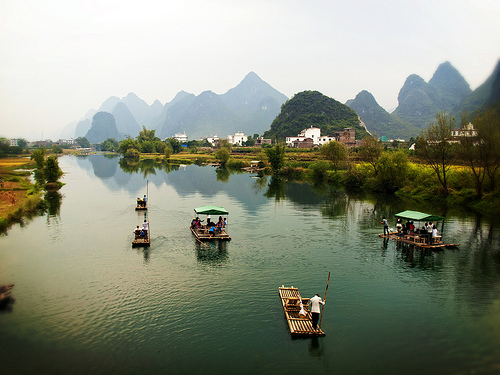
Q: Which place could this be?
A: It is a river.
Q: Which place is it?
A: It is a river.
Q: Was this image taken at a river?
A: Yes, it was taken in a river.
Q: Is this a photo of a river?
A: Yes, it is showing a river.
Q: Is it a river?
A: Yes, it is a river.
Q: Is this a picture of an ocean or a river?
A: It is showing a river.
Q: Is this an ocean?
A: No, it is a river.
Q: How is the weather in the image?
A: It is foggy.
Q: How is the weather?
A: It is foggy.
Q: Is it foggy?
A: Yes, it is foggy.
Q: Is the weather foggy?
A: Yes, it is foggy.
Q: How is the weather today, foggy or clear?
A: It is foggy.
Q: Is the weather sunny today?
A: No, it is foggy.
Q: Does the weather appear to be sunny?
A: No, it is foggy.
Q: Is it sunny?
A: No, it is foggy.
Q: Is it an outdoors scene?
A: Yes, it is outdoors.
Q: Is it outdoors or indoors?
A: It is outdoors.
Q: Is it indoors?
A: No, it is outdoors.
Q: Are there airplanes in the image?
A: No, there are no airplanes.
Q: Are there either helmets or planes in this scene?
A: No, there are no planes or helmets.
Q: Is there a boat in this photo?
A: Yes, there is a boat.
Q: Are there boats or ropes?
A: Yes, there is a boat.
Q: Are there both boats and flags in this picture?
A: No, there is a boat but no flags.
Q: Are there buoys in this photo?
A: No, there are no buoys.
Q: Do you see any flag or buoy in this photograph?
A: No, there are no buoys or flags.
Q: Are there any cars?
A: No, there are no cars.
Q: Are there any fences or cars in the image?
A: No, there are no cars or fences.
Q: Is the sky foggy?
A: Yes, the sky is foggy.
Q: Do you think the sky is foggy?
A: Yes, the sky is foggy.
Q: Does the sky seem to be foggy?
A: Yes, the sky is foggy.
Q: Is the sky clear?
A: No, the sky is foggy.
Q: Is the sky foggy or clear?
A: The sky is foggy.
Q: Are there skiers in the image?
A: No, there are no skiers.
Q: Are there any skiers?
A: No, there are no skiers.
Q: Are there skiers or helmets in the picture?
A: No, there are no skiers or helmets.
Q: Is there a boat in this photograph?
A: Yes, there is a boat.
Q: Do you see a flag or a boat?
A: Yes, there is a boat.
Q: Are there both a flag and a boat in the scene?
A: No, there is a boat but no flags.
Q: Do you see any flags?
A: No, there are no flags.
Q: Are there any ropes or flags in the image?
A: No, there are no flags or ropes.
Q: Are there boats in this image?
A: Yes, there is a boat.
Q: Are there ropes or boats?
A: Yes, there is a boat.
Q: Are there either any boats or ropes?
A: Yes, there is a boat.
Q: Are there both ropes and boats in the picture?
A: No, there is a boat but no ropes.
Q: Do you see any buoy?
A: No, there are no buoys.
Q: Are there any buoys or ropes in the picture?
A: No, there are no buoys or ropes.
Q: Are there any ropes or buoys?
A: No, there are no buoys or ropes.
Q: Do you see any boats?
A: Yes, there is a boat.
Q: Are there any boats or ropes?
A: Yes, there is a boat.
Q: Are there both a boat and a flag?
A: No, there is a boat but no flags.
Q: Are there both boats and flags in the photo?
A: No, there is a boat but no flags.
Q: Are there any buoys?
A: No, there are no buoys.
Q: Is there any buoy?
A: No, there are no buoys.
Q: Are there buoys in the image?
A: No, there are no buoys.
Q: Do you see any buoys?
A: No, there are no buoys.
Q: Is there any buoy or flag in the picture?
A: No, there are no buoys or flags.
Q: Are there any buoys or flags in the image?
A: No, there are no buoys or flags.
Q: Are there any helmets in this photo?
A: No, there are no helmets.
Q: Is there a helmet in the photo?
A: No, there are no helmets.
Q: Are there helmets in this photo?
A: No, there are no helmets.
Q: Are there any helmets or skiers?
A: No, there are no helmets or skiers.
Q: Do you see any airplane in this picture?
A: No, there are no airplanes.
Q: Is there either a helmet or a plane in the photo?
A: No, there are no airplanes or helmets.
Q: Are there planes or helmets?
A: No, there are no planes or helmets.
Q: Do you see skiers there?
A: No, there are no skiers.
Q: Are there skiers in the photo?
A: No, there are no skiers.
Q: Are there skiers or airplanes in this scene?
A: No, there are no skiers or airplanes.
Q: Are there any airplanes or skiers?
A: No, there are no skiers or airplanes.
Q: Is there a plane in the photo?
A: No, there are no airplanes.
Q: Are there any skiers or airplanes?
A: No, there are no airplanes or skiers.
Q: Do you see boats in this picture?
A: Yes, there is a boat.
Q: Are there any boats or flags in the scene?
A: Yes, there is a boat.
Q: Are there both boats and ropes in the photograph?
A: No, there is a boat but no ropes.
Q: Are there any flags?
A: No, there are no flags.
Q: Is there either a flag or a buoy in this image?
A: No, there are no flags or buoys.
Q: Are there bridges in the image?
A: No, there are no bridges.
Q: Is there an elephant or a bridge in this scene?
A: No, there are no bridges or elephants.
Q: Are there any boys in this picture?
A: No, there are no boys.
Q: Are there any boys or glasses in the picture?
A: No, there are no boys or glasses.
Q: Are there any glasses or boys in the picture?
A: No, there are no boys or glasses.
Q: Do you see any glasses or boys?
A: No, there are no boys or glasses.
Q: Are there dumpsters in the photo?
A: No, there are no dumpsters.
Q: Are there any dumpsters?
A: No, there are no dumpsters.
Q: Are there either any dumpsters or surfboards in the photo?
A: No, there are no dumpsters or surfboards.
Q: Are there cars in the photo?
A: No, there are no cars.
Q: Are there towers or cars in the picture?
A: No, there are no cars or towers.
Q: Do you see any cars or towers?
A: No, there are no cars or towers.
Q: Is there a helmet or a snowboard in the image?
A: No, there are no helmets or snowboards.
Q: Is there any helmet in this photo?
A: No, there are no helmets.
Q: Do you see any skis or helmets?
A: No, there are no helmets or skis.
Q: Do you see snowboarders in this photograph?
A: No, there are no snowboarders.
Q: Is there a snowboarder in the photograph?
A: No, there are no snowboarders.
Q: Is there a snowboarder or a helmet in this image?
A: No, there are no snowboarders or helmets.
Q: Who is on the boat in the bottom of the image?
A: The man is on the boat.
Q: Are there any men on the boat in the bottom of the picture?
A: Yes, there is a man on the boat.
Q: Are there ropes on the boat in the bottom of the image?
A: No, there is a man on the boat.